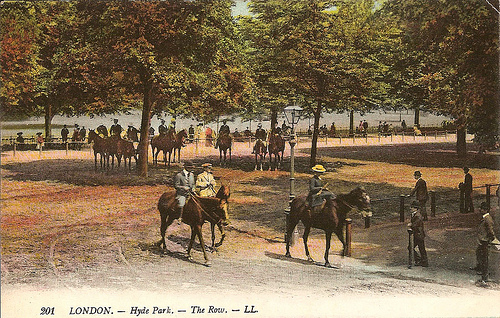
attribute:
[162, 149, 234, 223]
woman — wearing, riding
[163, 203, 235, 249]
horse — under, standing, brown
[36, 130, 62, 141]
fence — wood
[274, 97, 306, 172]
post — behind, metal, lamp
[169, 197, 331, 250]
horses — under, brown, grouped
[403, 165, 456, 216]
man — leaning, standing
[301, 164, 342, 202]
hat — yellow, black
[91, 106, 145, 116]
water — lake, behind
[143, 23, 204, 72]
tree — changing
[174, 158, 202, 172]
hat — black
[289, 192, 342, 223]
type — black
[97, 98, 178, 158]
gentleman — watching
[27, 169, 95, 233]
grass — colorful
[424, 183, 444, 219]
posts — wooden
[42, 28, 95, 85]
colors — fall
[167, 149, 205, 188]
person — wearing, riding, standing, sitting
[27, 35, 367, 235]
painting — printed, london, victorian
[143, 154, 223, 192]
men — riding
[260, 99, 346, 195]
light — victorian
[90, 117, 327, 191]
people — several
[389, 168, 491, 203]
men — leaning